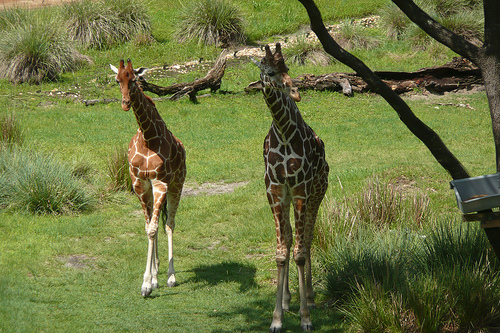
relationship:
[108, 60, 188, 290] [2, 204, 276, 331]
giraffe standing in grass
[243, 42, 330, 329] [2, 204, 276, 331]
giraffe standing in grass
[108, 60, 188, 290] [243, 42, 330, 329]
giraffe next to giraffe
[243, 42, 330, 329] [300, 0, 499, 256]
giraffe under tree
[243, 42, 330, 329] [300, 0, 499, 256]
giraffe next to tree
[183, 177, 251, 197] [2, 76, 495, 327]
dirt in field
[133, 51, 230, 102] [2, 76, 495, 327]
log on field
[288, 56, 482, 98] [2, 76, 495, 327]
log on field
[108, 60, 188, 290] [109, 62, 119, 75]
giraffe has ear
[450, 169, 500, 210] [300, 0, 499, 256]
box on tree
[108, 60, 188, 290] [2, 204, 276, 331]
giraffe in grass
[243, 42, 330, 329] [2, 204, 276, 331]
giraffe in grass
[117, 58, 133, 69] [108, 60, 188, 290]
horns on giraffe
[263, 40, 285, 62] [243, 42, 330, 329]
horns on giraffe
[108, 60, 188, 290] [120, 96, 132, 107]
giraffe has nose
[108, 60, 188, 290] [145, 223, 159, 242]
giraffe has knees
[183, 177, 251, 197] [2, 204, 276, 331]
dirt next to grass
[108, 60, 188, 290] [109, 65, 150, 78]
giraffe has ears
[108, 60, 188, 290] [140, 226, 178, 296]
giraffe has legs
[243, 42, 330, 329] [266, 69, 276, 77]
giraffe has eye